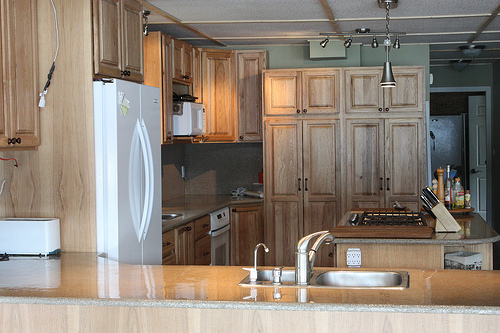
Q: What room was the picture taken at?
A: It was taken at the kitchen.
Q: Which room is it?
A: It is a kitchen.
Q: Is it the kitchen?
A: Yes, it is the kitchen.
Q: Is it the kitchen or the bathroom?
A: It is the kitchen.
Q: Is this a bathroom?
A: No, it is a kitchen.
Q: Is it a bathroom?
A: No, it is a kitchen.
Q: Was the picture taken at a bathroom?
A: No, the picture was taken in a kitchen.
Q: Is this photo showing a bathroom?
A: No, the picture is showing a kitchen.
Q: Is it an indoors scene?
A: Yes, it is indoors.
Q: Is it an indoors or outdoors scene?
A: It is indoors.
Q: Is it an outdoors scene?
A: No, it is indoors.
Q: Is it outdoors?
A: No, it is indoors.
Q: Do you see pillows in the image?
A: No, there are no pillows.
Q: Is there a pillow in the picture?
A: No, there are no pillows.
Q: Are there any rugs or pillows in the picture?
A: No, there are no pillows or rugs.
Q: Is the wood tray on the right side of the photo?
A: Yes, the tray is on the right of the image.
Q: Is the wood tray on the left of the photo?
A: No, the tray is on the right of the image.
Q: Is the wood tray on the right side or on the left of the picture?
A: The tray is on the right of the image.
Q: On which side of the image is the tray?
A: The tray is on the right of the image.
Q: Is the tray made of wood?
A: Yes, the tray is made of wood.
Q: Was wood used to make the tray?
A: Yes, the tray is made of wood.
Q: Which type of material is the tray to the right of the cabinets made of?
A: The tray is made of wood.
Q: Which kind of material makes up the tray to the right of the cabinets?
A: The tray is made of wood.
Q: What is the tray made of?
A: The tray is made of wood.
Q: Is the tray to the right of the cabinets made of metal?
A: No, the tray is made of wood.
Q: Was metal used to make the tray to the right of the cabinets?
A: No, the tray is made of wood.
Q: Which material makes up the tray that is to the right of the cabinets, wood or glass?
A: The tray is made of wood.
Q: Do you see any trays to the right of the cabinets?
A: Yes, there is a tray to the right of the cabinets.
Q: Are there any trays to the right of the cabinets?
A: Yes, there is a tray to the right of the cabinets.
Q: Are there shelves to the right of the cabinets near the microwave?
A: No, there is a tray to the right of the cabinets.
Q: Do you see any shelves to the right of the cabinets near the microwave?
A: No, there is a tray to the right of the cabinets.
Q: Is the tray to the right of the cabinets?
A: Yes, the tray is to the right of the cabinets.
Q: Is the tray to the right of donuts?
A: No, the tray is to the right of the cabinets.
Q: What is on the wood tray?
A: The condiment is on the tray.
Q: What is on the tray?
A: The condiment is on the tray.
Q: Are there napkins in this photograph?
A: No, there are no napkins.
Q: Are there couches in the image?
A: No, there are no couches.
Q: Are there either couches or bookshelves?
A: No, there are no couches or bookshelves.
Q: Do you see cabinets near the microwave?
A: Yes, there are cabinets near the microwave.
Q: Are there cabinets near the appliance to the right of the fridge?
A: Yes, there are cabinets near the microwave.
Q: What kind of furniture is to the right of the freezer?
A: The pieces of furniture are cabinets.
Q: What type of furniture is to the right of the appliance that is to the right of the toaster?
A: The pieces of furniture are cabinets.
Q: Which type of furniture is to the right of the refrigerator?
A: The pieces of furniture are cabinets.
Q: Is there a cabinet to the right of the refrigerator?
A: Yes, there are cabinets to the right of the refrigerator.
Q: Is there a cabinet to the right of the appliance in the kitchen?
A: Yes, there are cabinets to the right of the refrigerator.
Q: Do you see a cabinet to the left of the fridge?
A: No, the cabinets are to the right of the fridge.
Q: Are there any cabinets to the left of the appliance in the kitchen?
A: No, the cabinets are to the right of the fridge.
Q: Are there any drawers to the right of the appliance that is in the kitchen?
A: No, there are cabinets to the right of the fridge.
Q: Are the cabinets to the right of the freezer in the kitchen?
A: Yes, the cabinets are to the right of the refrigerator.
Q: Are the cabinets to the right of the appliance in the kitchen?
A: Yes, the cabinets are to the right of the refrigerator.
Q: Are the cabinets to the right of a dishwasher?
A: No, the cabinets are to the right of the refrigerator.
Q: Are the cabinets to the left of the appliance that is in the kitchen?
A: No, the cabinets are to the right of the fridge.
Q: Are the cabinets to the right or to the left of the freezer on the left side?
A: The cabinets are to the right of the freezer.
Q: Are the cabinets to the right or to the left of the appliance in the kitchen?
A: The cabinets are to the right of the freezer.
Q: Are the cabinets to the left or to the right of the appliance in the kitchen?
A: The cabinets are to the right of the freezer.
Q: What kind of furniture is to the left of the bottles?
A: The pieces of furniture are cabinets.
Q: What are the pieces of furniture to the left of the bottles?
A: The pieces of furniture are cabinets.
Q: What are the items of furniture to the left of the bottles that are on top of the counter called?
A: The pieces of furniture are cabinets.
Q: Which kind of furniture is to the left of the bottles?
A: The pieces of furniture are cabinets.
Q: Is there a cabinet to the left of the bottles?
A: Yes, there are cabinets to the left of the bottles.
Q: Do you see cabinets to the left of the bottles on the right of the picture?
A: Yes, there are cabinets to the left of the bottles.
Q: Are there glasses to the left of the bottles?
A: No, there are cabinets to the left of the bottles.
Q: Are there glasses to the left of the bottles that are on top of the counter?
A: No, there are cabinets to the left of the bottles.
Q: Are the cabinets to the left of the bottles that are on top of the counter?
A: Yes, the cabinets are to the left of the bottles.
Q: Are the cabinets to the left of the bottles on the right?
A: Yes, the cabinets are to the left of the bottles.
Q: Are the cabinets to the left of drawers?
A: No, the cabinets are to the left of the bottles.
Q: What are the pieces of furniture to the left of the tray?
A: The pieces of furniture are cabinets.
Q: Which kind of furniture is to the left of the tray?
A: The pieces of furniture are cabinets.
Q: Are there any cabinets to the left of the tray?
A: Yes, there are cabinets to the left of the tray.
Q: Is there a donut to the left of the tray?
A: No, there are cabinets to the left of the tray.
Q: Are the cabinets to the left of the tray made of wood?
A: Yes, the cabinets are to the left of the tray.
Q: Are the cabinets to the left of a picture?
A: No, the cabinets are to the left of the tray.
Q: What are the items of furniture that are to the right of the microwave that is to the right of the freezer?
A: The pieces of furniture are cabinets.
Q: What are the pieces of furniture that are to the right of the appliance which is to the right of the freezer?
A: The pieces of furniture are cabinets.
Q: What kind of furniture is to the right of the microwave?
A: The pieces of furniture are cabinets.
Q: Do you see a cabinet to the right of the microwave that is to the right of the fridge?
A: Yes, there are cabinets to the right of the microwave.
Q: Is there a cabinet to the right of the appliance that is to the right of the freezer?
A: Yes, there are cabinets to the right of the microwave.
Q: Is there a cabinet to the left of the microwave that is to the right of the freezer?
A: No, the cabinets are to the right of the microwave.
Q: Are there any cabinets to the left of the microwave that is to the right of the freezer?
A: No, the cabinets are to the right of the microwave.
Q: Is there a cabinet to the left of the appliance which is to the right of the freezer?
A: No, the cabinets are to the right of the microwave.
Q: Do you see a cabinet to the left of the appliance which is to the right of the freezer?
A: No, the cabinets are to the right of the microwave.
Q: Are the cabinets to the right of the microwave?
A: Yes, the cabinets are to the right of the microwave.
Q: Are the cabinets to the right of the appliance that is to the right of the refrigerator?
A: Yes, the cabinets are to the right of the microwave.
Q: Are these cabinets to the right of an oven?
A: No, the cabinets are to the right of the microwave.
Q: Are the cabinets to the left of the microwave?
A: No, the cabinets are to the right of the microwave.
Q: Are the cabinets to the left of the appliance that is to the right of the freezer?
A: No, the cabinets are to the right of the microwave.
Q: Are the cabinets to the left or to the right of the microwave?
A: The cabinets are to the right of the microwave.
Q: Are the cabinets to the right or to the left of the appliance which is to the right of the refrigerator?
A: The cabinets are to the right of the microwave.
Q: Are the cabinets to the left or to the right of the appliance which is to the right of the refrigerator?
A: The cabinets are to the right of the microwave.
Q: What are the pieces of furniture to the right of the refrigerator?
A: The pieces of furniture are cupboards.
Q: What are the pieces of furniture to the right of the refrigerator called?
A: The pieces of furniture are cupboards.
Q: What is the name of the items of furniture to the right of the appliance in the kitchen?
A: The pieces of furniture are cupboards.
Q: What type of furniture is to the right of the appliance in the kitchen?
A: The pieces of furniture are cupboards.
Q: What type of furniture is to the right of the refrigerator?
A: The pieces of furniture are cupboards.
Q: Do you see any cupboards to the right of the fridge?
A: Yes, there are cupboards to the right of the fridge.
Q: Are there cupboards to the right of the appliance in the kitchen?
A: Yes, there are cupboards to the right of the fridge.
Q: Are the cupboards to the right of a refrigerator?
A: Yes, the cupboards are to the right of a refrigerator.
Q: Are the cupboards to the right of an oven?
A: No, the cupboards are to the right of a refrigerator.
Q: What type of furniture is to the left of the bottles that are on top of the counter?
A: The pieces of furniture are cupboards.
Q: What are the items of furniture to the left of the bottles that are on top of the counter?
A: The pieces of furniture are cupboards.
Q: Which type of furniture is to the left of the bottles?
A: The pieces of furniture are cupboards.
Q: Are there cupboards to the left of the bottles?
A: Yes, there are cupboards to the left of the bottles.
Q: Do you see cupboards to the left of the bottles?
A: Yes, there are cupboards to the left of the bottles.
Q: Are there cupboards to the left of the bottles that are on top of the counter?
A: Yes, there are cupboards to the left of the bottles.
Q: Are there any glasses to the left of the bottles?
A: No, there are cupboards to the left of the bottles.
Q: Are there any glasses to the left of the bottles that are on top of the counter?
A: No, there are cupboards to the left of the bottles.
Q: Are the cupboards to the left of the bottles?
A: Yes, the cupboards are to the left of the bottles.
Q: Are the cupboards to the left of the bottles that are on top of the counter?
A: Yes, the cupboards are to the left of the bottles.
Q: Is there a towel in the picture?
A: No, there are no towels.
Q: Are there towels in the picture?
A: No, there are no towels.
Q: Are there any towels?
A: No, there are no towels.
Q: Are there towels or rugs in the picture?
A: No, there are no towels or rugs.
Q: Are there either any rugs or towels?
A: No, there are no towels or rugs.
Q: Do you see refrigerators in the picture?
A: Yes, there is a refrigerator.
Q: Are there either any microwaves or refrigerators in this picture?
A: Yes, there is a refrigerator.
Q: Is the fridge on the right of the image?
A: No, the fridge is on the left of the image.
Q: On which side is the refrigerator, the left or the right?
A: The refrigerator is on the left of the image.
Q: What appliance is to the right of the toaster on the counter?
A: The appliance is a refrigerator.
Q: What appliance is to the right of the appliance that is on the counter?
A: The appliance is a refrigerator.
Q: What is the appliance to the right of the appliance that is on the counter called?
A: The appliance is a refrigerator.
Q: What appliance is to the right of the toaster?
A: The appliance is a refrigerator.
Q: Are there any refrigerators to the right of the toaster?
A: Yes, there is a refrigerator to the right of the toaster.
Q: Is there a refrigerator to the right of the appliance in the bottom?
A: Yes, there is a refrigerator to the right of the toaster.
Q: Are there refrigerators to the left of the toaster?
A: No, the refrigerator is to the right of the toaster.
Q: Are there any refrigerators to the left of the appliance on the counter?
A: No, the refrigerator is to the right of the toaster.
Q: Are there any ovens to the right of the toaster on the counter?
A: No, there is a refrigerator to the right of the toaster.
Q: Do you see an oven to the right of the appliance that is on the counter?
A: No, there is a refrigerator to the right of the toaster.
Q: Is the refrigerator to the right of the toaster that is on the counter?
A: Yes, the refrigerator is to the right of the toaster.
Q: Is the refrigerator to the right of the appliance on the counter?
A: Yes, the refrigerator is to the right of the toaster.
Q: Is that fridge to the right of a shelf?
A: No, the fridge is to the right of the toaster.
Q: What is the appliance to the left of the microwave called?
A: The appliance is a refrigerator.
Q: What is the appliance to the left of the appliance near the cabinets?
A: The appliance is a refrigerator.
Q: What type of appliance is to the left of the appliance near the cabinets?
A: The appliance is a refrigerator.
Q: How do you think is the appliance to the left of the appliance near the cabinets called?
A: The appliance is a refrigerator.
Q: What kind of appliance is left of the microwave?
A: The appliance is a refrigerator.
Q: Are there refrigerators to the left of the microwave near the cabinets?
A: Yes, there is a refrigerator to the left of the microwave.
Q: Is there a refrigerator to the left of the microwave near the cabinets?
A: Yes, there is a refrigerator to the left of the microwave.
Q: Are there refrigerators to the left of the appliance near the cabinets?
A: Yes, there is a refrigerator to the left of the microwave.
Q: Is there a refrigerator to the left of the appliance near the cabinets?
A: Yes, there is a refrigerator to the left of the microwave.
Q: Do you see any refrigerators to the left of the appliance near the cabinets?
A: Yes, there is a refrigerator to the left of the microwave.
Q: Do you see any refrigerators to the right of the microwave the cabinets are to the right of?
A: No, the refrigerator is to the left of the microwave.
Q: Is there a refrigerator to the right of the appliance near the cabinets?
A: No, the refrigerator is to the left of the microwave.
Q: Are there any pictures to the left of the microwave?
A: No, there is a refrigerator to the left of the microwave.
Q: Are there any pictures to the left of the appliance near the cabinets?
A: No, there is a refrigerator to the left of the microwave.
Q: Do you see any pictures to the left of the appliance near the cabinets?
A: No, there is a refrigerator to the left of the microwave.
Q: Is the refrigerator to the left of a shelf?
A: No, the refrigerator is to the left of a microwave.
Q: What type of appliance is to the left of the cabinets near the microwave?
A: The appliance is a refrigerator.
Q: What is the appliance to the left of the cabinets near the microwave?
A: The appliance is a refrigerator.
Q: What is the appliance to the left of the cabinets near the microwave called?
A: The appliance is a refrigerator.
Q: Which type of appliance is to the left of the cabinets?
A: The appliance is a refrigerator.